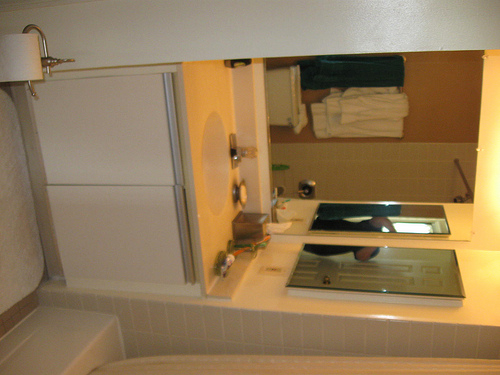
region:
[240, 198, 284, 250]
tissue on the sink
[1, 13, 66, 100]
toilet paper in the holder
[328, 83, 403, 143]
white towels hanging on the rod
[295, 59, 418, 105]
blue towel hanging on the rod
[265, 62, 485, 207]
mirror above the sink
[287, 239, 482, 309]
small mirror on the wall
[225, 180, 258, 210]
soap in the soap dish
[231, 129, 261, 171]
faucet above the sink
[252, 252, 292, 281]
outlet on the wall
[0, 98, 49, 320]
rug on the floor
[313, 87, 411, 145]
Towel on a rack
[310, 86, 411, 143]
Towels on a rack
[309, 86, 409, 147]
Towel is on a rack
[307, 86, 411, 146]
Towels are on a rack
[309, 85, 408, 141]
White towel on a rack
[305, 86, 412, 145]
White towel is on a rack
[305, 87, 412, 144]
White towels are on a rack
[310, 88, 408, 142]
Towel on a towel rack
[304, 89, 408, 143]
Towels on a towel rack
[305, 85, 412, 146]
White towels on a towel rack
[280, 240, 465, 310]
medicine cabinet on the wall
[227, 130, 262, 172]
faucet in a bathroom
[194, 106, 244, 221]
sink in a bathroom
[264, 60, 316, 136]
reflection of a garbage can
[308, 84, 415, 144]
towels hanging on a rack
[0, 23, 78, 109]
toilet paper on a holder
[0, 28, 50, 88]
white roll of toilet paper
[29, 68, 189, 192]
white door of cabinet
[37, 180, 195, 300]
white door of cabinet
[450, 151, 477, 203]
shower curtain rod in shower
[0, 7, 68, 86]
a roll of toilet paper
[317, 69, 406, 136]
white towels hanging on towel rod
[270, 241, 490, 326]
a mirror hanging on the wall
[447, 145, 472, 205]
a metal shower curtain rod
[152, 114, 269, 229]
a white bathroom sink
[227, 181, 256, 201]
a white bar of soap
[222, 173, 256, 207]
a bar of soap in a soap dish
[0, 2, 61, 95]
a roll of toilet paper on a holder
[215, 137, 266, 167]
a bathroom sink faucet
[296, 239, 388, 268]
a person's reflection in a mirror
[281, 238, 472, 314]
Side mirror next to the sink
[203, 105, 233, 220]
Huge sink whole in the counter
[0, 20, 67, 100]
White toilet paper roll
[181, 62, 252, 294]
White sink counter top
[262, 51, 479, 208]
Large silver mirror over sink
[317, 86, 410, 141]
Reflection of a white towel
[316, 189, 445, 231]
Reflection of the side mirror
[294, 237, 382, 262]
Reflection of the man's arm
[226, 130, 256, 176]
Silver and glass faucet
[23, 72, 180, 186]
White door under sink